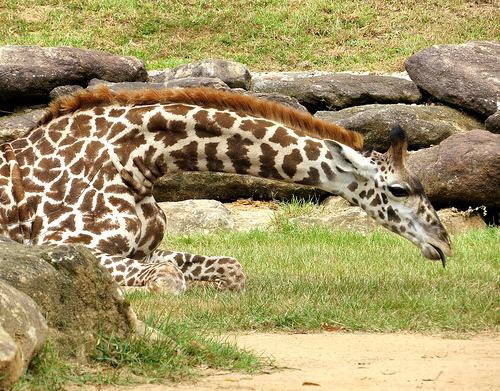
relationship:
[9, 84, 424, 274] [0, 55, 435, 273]
giraffe bending over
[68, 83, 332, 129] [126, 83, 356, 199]
mane on neck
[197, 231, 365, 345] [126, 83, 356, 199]
grass under neck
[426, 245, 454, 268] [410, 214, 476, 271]
tongue in mouth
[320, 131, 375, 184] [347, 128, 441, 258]
ear on head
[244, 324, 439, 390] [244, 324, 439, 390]
dirt in dirt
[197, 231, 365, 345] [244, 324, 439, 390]
grass behind pile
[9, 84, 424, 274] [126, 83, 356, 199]
giraffe arching neck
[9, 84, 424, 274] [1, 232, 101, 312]
giraffe near rocks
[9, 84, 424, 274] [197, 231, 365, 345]
giraffe on grass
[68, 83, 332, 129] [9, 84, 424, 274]
mane on giraffe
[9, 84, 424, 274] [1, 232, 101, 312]
giraffe between rocks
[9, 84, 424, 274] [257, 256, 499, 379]
giraffe close to ground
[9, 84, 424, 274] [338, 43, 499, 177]
giraffe near cluster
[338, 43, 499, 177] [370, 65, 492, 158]
cluster in cluster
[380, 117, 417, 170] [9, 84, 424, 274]
horns on giraffe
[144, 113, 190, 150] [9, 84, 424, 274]
spots on giraffe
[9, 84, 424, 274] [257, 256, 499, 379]
giraffe on ground